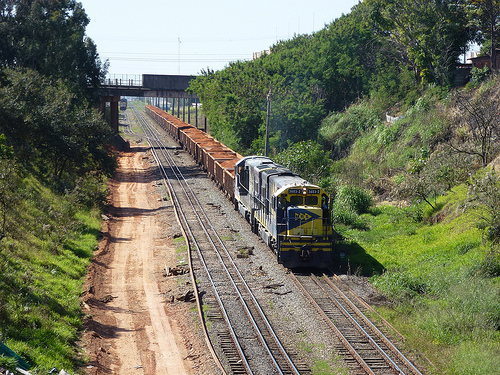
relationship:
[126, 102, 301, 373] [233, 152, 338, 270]
track near train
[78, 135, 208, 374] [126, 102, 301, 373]
dirt near track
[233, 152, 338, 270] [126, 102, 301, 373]
train near track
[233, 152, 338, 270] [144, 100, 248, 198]
train with train cars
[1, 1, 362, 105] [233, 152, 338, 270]
sky above train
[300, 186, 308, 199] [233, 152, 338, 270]
lights of train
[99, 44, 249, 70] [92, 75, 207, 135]
electrical wires above bridge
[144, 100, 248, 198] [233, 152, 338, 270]
train cars behind train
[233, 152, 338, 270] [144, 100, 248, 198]
train hauling train cars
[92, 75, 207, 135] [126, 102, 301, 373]
bridge over track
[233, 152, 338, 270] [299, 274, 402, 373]
train on track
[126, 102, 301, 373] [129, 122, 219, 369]
track surrounded by rocks